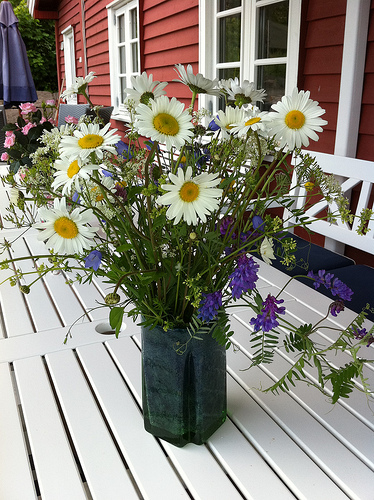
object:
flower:
[33, 191, 103, 259]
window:
[119, 74, 128, 108]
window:
[255, 3, 289, 60]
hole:
[95, 318, 122, 338]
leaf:
[108, 303, 124, 340]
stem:
[111, 270, 133, 296]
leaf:
[340, 386, 355, 395]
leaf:
[282, 379, 291, 392]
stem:
[261, 352, 307, 394]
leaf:
[294, 162, 303, 178]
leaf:
[149, 163, 163, 179]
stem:
[142, 143, 156, 261]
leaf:
[350, 326, 358, 335]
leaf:
[264, 331, 280, 340]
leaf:
[249, 332, 262, 342]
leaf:
[249, 343, 261, 350]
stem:
[260, 329, 265, 357]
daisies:
[156, 166, 223, 227]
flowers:
[20, 121, 33, 137]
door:
[61, 25, 76, 107]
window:
[117, 13, 125, 45]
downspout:
[324, 0, 371, 256]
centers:
[286, 110, 303, 132]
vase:
[140, 312, 227, 448]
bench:
[220, 148, 373, 328]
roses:
[2, 133, 17, 151]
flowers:
[131, 94, 195, 152]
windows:
[119, 48, 127, 78]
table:
[0, 164, 374, 499]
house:
[0, 0, 374, 499]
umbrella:
[0, 0, 40, 106]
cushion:
[248, 229, 357, 278]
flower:
[199, 287, 222, 323]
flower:
[261, 86, 327, 152]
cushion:
[295, 260, 373, 324]